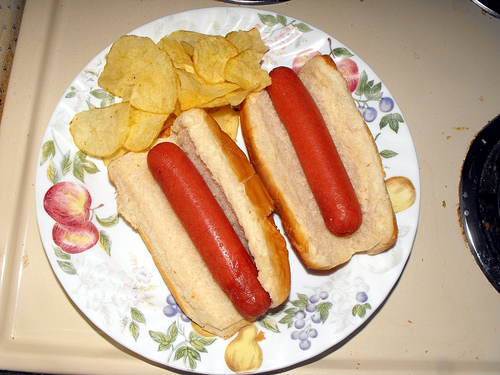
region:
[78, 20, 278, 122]
Potatoe chips on a plate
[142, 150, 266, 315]
Hot dog weiner that is cooked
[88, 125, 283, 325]
One hot dog on hot dog bun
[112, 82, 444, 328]
Two hot dogs on plate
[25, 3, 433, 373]
Plate of food for dinner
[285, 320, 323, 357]
Purple grapes on a plate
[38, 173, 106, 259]
Apple design on plate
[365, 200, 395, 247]
Hot dog bun bread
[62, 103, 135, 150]
One potato chip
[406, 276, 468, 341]
Table that plate is sitting on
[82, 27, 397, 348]
two hotdogs on a plate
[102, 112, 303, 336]
a hotdog in a bun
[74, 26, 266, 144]
potato chips on a plate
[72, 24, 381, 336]
potato chips and two hotdogs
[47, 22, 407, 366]
hotdogs on a floral plate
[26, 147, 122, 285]
flower decoration on plate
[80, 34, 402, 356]
chips and hotdogs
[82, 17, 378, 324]
chips and hotdogs on plate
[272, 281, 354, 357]
decorative grapes on plate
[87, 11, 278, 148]
chips next to hotdogs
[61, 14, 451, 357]
hots dogs and chips on a dish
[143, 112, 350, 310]
two hot dogs with buns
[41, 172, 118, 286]
apple design on the plate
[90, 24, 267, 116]
potato chips are on the plate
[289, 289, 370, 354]
grape design on the plate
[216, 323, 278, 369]
pear design on the plate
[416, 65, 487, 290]
crumbs are on the surface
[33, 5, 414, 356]
white plate is round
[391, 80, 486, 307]
plate is sitting on top of the stove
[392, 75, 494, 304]
plate is next to the rim of a burner on the stove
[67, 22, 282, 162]
POTATO CHIPS ON A PLATE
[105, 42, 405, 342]
TWO HOT DOGS ON A PLATE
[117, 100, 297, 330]
A HOT DOG ON A BUN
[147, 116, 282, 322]
A PICTURE OF A HOT DOG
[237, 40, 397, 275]
A HOT DOG BUN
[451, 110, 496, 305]
A PICTURE OF THE EDGE OF A STOVE BURNER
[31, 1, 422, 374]
HOT DOGS AND CHIPS ON A PLATE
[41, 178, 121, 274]
TWO APPLES PAINTED ON A PLATE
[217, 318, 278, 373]
A PAINTED PEAR ON A PLAY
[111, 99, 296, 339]
A HOT DOG ON A WHITE BREAD BUN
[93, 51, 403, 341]
two plain hotdogs on buns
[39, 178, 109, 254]
two peaches painted on white plate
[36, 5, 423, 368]
round white plate with fruit theme as design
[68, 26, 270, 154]
yellow potato chips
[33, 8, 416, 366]
one plate of two plain hot dogs and potato chips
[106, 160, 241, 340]
tan white bread hot dog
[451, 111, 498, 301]
silver stone burner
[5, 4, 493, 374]
white metal stove top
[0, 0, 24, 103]
blue and white wallpaper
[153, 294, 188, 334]
purple grapes painted on white plate